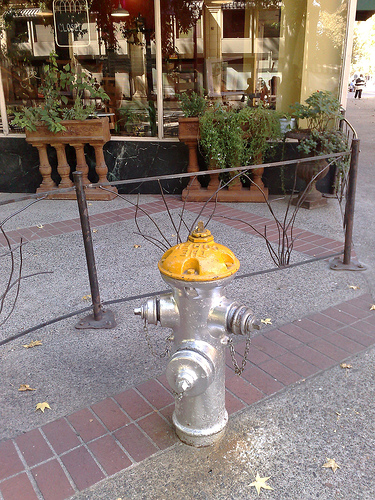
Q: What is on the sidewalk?
A: A hydrant.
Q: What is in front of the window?
A: Plants.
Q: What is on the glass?
A: A reflection.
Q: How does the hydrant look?
A: Yellow and silver.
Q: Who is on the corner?
A: A person.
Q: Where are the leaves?
A: On the ground.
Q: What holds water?
A: The hydrant?.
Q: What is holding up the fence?
A: Two poles.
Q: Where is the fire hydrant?
A: On the sidewalk.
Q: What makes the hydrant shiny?
A: Silver paint.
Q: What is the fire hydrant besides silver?
A: Yellow.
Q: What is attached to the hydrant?
A: A silver chain.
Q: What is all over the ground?
A: Leaves.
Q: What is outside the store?
A: Potted plants.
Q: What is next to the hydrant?
A: Bricks.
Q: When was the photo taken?
A: Daytime.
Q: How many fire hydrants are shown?
A: One.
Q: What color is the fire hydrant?
A: Silver and yellow.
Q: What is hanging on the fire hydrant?
A: Chains.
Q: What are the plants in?
A: Planters.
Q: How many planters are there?
A: Three.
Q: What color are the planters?
A: Brown.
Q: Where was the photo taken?
A: In front of a restaurant.